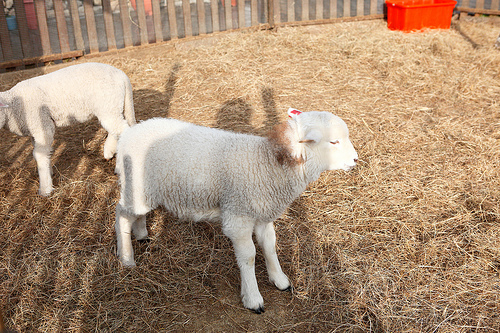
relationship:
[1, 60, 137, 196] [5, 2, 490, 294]
sheep in pen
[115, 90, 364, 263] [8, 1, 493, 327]
sheep in pen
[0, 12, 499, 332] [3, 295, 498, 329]
hay on ground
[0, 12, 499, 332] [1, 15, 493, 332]
hay on ground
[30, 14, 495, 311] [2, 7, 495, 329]
pen lined straw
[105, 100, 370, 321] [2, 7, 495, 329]
lamb in straw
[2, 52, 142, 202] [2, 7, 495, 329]
lamb in straw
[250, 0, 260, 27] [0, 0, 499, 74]
slat on fence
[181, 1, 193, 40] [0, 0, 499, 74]
slat on fence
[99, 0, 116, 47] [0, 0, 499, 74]
slat on fence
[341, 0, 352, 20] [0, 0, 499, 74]
slat on fence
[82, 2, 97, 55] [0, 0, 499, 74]
slat on fence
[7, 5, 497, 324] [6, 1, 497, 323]
picture taken outdoors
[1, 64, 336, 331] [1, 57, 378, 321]
shadows on hay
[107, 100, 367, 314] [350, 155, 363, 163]
sheep has nose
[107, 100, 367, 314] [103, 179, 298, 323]
sheep has legs